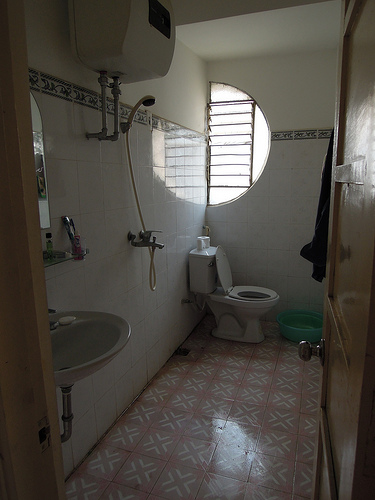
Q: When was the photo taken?
A: Daytime.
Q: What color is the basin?
A: Green.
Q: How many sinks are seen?
A: One.